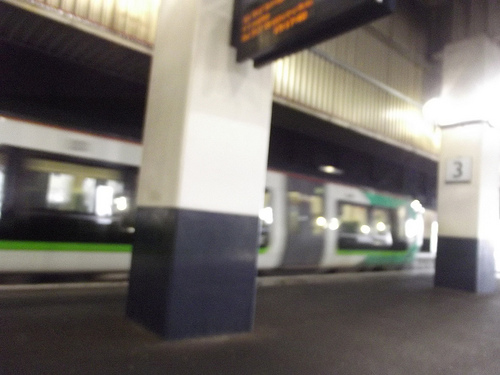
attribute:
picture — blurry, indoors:
[10, 19, 449, 320]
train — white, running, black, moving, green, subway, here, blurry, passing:
[8, 112, 415, 265]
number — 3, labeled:
[443, 144, 470, 179]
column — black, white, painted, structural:
[161, 71, 295, 237]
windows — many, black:
[20, 168, 123, 236]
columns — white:
[155, 81, 499, 244]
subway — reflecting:
[28, 152, 398, 232]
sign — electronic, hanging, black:
[226, 7, 446, 73]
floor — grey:
[306, 288, 466, 355]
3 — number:
[433, 139, 484, 195]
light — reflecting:
[314, 200, 410, 249]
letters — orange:
[237, 7, 267, 25]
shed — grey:
[5, 35, 195, 178]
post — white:
[150, 40, 234, 317]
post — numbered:
[436, 85, 480, 275]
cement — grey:
[272, 277, 451, 366]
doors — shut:
[279, 181, 338, 268]